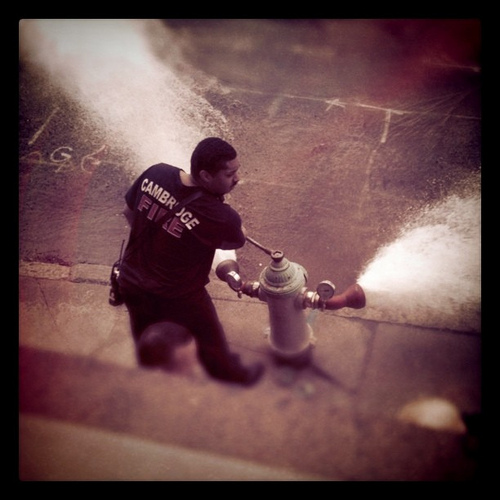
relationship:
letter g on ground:
[46, 139, 78, 168] [17, 30, 130, 253]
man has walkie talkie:
[101, 134, 273, 392] [104, 232, 127, 309]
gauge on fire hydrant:
[315, 278, 337, 301] [216, 235, 377, 373]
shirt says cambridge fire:
[107, 161, 252, 300] [133, 174, 200, 237]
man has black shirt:
[101, 134, 273, 392] [107, 161, 252, 300]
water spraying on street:
[363, 199, 487, 322] [276, 21, 499, 254]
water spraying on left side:
[363, 199, 487, 322] [432, 8, 476, 474]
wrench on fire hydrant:
[243, 228, 290, 265] [216, 235, 377, 373]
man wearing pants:
[101, 134, 273, 392] [111, 264, 253, 380]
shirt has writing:
[107, 161, 252, 300] [133, 174, 200, 237]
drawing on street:
[19, 103, 110, 183] [17, 30, 130, 253]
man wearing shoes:
[101, 134, 273, 392] [207, 358, 269, 387]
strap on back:
[133, 174, 200, 237] [122, 163, 214, 281]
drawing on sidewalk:
[19, 126, 120, 185] [17, 30, 130, 253]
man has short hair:
[101, 134, 273, 392] [178, 127, 239, 182]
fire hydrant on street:
[216, 235, 377, 373] [276, 21, 499, 254]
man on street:
[101, 134, 273, 392] [276, 21, 499, 254]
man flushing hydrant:
[101, 134, 273, 392] [216, 235, 377, 373]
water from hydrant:
[363, 199, 487, 322] [216, 235, 377, 373]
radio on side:
[104, 232, 127, 309] [112, 173, 148, 329]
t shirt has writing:
[107, 161, 252, 300] [133, 174, 200, 237]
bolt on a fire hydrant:
[273, 249, 284, 264] [216, 235, 377, 373]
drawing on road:
[19, 103, 110, 183] [17, 30, 130, 253]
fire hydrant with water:
[216, 235, 377, 373] [363, 199, 487, 322]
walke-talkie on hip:
[104, 232, 127, 309] [108, 261, 209, 316]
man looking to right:
[101, 134, 273, 392] [432, 8, 476, 474]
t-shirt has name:
[107, 161, 252, 300] [133, 174, 200, 237]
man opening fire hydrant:
[101, 134, 273, 392] [216, 235, 377, 373]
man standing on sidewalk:
[101, 134, 273, 392] [14, 253, 475, 473]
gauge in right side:
[315, 278, 337, 301] [429, 17, 476, 478]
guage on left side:
[222, 265, 245, 299] [24, 21, 68, 476]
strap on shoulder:
[133, 174, 200, 237] [188, 191, 244, 242]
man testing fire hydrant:
[101, 134, 273, 392] [216, 235, 377, 373]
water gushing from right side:
[363, 199, 487, 322] [429, 17, 476, 478]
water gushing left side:
[48, 20, 200, 144] [24, 21, 68, 476]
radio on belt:
[104, 232, 127, 309] [115, 251, 189, 295]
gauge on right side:
[315, 278, 337, 301] [429, 17, 476, 478]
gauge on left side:
[222, 265, 245, 299] [24, 21, 68, 476]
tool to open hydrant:
[243, 228, 290, 265] [216, 235, 377, 373]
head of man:
[393, 385, 467, 435] [95, 136, 284, 418]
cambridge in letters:
[133, 174, 200, 237] [134, 172, 208, 242]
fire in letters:
[133, 192, 185, 242] [129, 193, 189, 245]